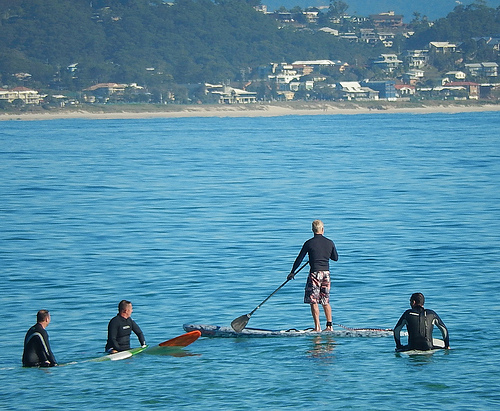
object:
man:
[286, 219, 339, 331]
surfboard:
[183, 323, 410, 341]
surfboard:
[155, 330, 202, 347]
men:
[103, 300, 147, 355]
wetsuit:
[105, 314, 146, 351]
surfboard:
[38, 345, 151, 370]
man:
[21, 308, 58, 370]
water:
[0, 110, 500, 411]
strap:
[326, 321, 333, 326]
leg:
[322, 287, 334, 331]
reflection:
[305, 340, 341, 363]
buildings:
[197, 82, 258, 104]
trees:
[79, 43, 105, 87]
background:
[0, 0, 497, 113]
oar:
[229, 259, 311, 332]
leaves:
[159, 41, 175, 54]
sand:
[249, 110, 272, 116]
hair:
[312, 220, 322, 232]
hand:
[287, 272, 294, 280]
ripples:
[144, 174, 313, 219]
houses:
[82, 81, 148, 103]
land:
[6, 95, 500, 122]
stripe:
[257, 306, 261, 309]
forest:
[1, 0, 384, 102]